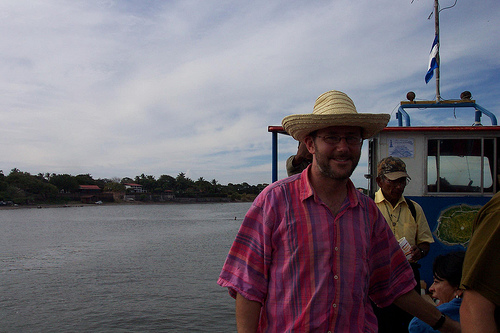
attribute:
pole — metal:
[423, 3, 448, 100]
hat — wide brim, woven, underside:
[277, 85, 397, 137]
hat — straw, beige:
[279, 87, 394, 143]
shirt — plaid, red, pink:
[214, 160, 421, 332]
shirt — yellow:
[371, 189, 445, 261]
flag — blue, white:
[411, 35, 459, 80]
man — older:
[368, 155, 435, 293]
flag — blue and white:
[408, 27, 468, 82]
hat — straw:
[280, 90, 390, 141]